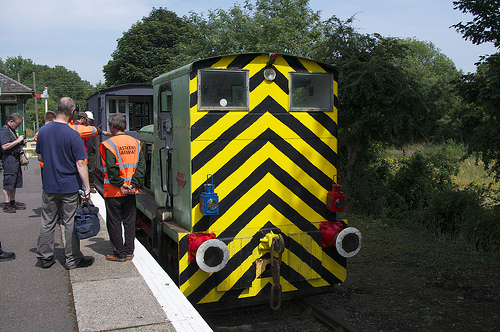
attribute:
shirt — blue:
[34, 122, 88, 194]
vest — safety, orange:
[100, 133, 142, 198]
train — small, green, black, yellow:
[75, 54, 365, 314]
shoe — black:
[79, 258, 94, 265]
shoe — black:
[37, 256, 57, 268]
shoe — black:
[1, 250, 15, 260]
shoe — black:
[5, 203, 16, 212]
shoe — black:
[15, 204, 26, 212]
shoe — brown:
[108, 252, 127, 263]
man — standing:
[2, 114, 28, 214]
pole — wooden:
[33, 72, 40, 139]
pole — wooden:
[16, 72, 27, 142]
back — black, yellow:
[179, 52, 362, 305]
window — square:
[200, 67, 247, 112]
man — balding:
[36, 97, 95, 270]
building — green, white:
[1, 71, 33, 145]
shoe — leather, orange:
[128, 254, 133, 260]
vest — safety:
[74, 124, 98, 153]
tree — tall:
[102, 9, 193, 85]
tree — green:
[381, 39, 465, 145]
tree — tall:
[173, 2, 328, 69]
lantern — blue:
[200, 182, 219, 218]